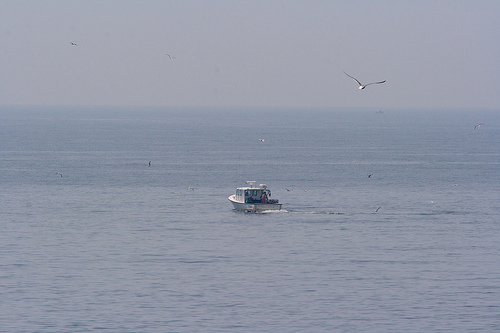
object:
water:
[1, 105, 500, 333]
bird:
[339, 71, 386, 93]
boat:
[226, 179, 283, 215]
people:
[259, 183, 272, 203]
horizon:
[0, 100, 498, 114]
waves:
[256, 208, 293, 215]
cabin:
[235, 176, 273, 205]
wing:
[365, 79, 386, 89]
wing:
[340, 71, 362, 87]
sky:
[0, 0, 500, 112]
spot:
[366, 173, 371, 179]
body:
[339, 71, 388, 91]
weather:
[2, 2, 500, 333]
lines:
[266, 188, 274, 197]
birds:
[164, 52, 181, 63]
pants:
[261, 199, 269, 207]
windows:
[239, 188, 243, 197]